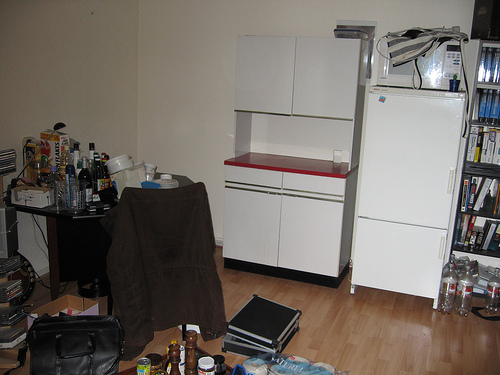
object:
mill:
[165, 339, 182, 374]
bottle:
[483, 268, 498, 315]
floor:
[0, 245, 498, 374]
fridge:
[349, 85, 469, 309]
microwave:
[372, 36, 480, 92]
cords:
[32, 213, 51, 249]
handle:
[53, 335, 97, 362]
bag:
[4, 311, 126, 374]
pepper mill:
[183, 329, 198, 374]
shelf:
[223, 152, 358, 178]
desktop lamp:
[6, 122, 67, 204]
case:
[220, 293, 302, 360]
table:
[5, 173, 195, 301]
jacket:
[106, 181, 229, 363]